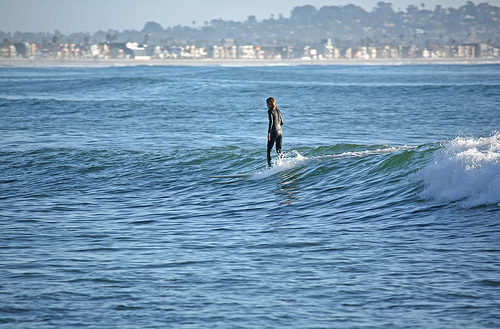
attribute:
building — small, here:
[9, 47, 19, 58]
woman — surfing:
[266, 97, 285, 168]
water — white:
[1, 66, 499, 329]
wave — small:
[283, 140, 499, 208]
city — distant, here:
[5, 39, 499, 60]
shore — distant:
[6, 58, 499, 65]